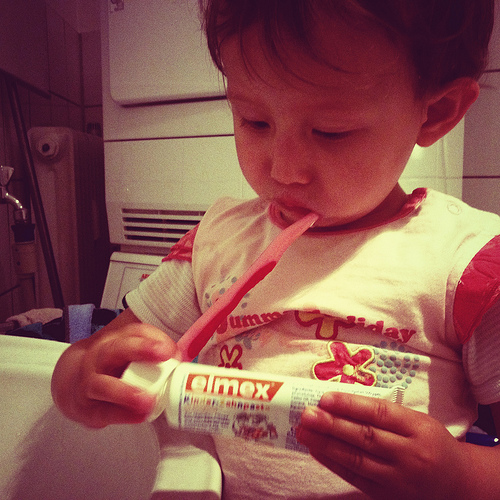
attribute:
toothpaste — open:
[119, 356, 404, 457]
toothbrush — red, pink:
[175, 212, 320, 365]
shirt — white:
[125, 196, 499, 497]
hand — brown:
[73, 324, 174, 429]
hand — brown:
[296, 393, 464, 495]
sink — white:
[3, 334, 158, 499]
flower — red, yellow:
[314, 341, 377, 388]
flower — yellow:
[294, 308, 354, 341]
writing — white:
[181, 373, 274, 399]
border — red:
[292, 311, 356, 338]